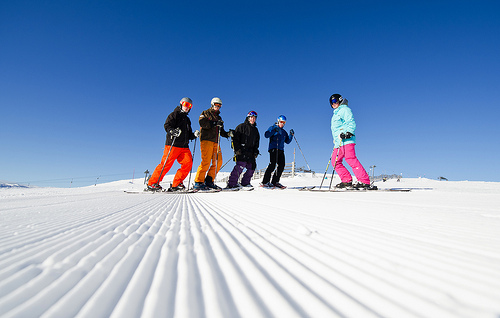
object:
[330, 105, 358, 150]
snow jacket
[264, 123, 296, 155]
snow jacket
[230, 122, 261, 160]
snow jacket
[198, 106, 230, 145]
snow jacket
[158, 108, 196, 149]
snow jacket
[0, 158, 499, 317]
outdoors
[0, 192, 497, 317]
tracks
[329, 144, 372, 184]
snow pants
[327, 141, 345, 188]
ski pole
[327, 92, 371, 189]
people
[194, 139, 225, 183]
pants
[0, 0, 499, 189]
sky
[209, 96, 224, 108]
white helmet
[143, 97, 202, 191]
skier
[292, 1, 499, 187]
right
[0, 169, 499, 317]
snow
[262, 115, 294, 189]
person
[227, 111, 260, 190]
person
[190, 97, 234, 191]
skier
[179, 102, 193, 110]
goggles